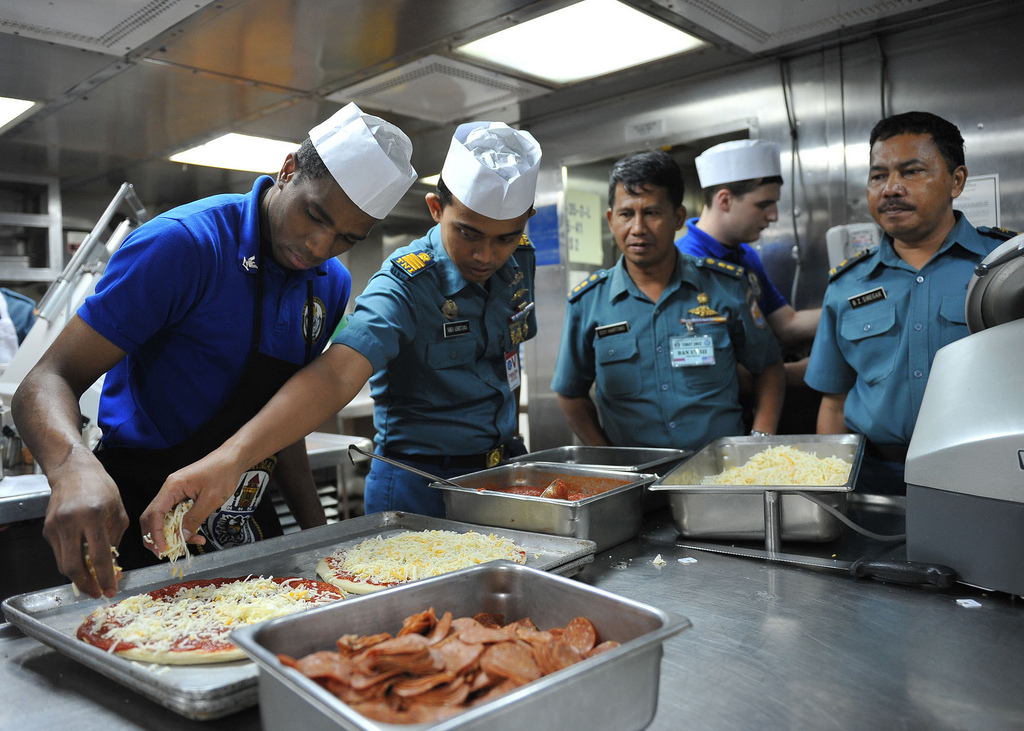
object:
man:
[551, 151, 783, 449]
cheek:
[655, 204, 672, 253]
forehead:
[310, 184, 375, 235]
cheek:
[268, 189, 303, 247]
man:
[11, 101, 414, 598]